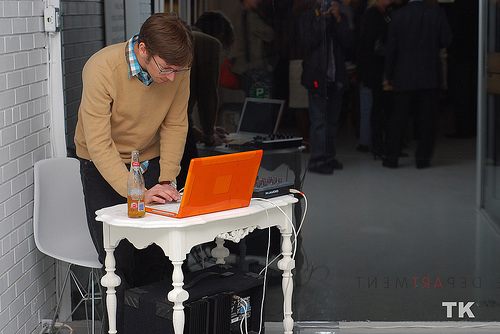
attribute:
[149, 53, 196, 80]
eye glasses — black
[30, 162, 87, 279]
chair — white 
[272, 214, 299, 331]
leg — white, table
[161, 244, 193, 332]
leg — white, table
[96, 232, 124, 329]
leg — white, table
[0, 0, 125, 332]
painted brick — white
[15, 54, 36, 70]
brick — white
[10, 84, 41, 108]
brick — white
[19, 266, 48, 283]
brick — white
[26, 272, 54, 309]
brick — white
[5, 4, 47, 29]
brick — white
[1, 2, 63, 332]
wall — brick, white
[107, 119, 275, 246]
laptop — orange 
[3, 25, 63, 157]
wall — white 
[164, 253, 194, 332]
leg — white, table, scrolling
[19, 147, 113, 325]
chair — white, plastic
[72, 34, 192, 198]
sweater — brown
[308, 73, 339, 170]
jeans — blue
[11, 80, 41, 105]
wall — white, brick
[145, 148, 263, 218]
laptop computer — plastic, orange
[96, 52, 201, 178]
sweater — brown 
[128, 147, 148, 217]
bottle — glass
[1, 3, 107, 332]
brick wall — white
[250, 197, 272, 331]
cord — white